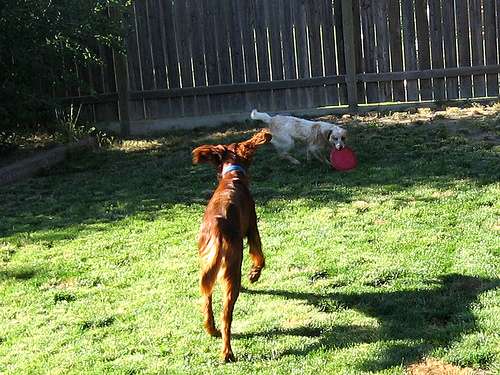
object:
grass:
[0, 114, 500, 375]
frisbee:
[329, 146, 357, 171]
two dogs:
[186, 106, 357, 366]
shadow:
[221, 270, 500, 374]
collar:
[222, 164, 249, 180]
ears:
[238, 129, 274, 155]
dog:
[249, 108, 349, 168]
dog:
[189, 124, 274, 367]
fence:
[0, 0, 500, 129]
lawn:
[42, 200, 168, 358]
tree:
[0, 0, 128, 129]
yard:
[0, 0, 500, 374]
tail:
[249, 108, 270, 125]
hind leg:
[273, 131, 301, 165]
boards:
[185, 0, 210, 90]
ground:
[0, 103, 500, 374]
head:
[326, 126, 349, 151]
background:
[0, 0, 124, 130]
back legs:
[219, 258, 241, 365]